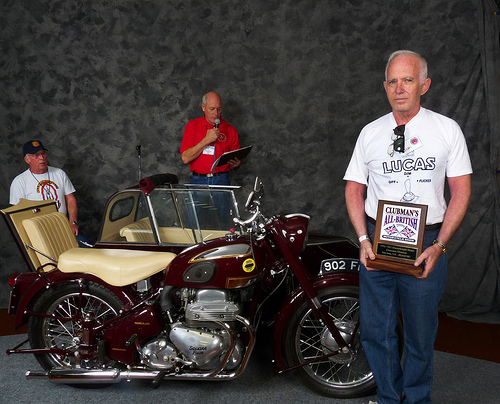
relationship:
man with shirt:
[344, 49, 474, 402] [337, 110, 473, 227]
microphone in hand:
[212, 116, 222, 133] [199, 125, 222, 145]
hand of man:
[199, 125, 222, 145] [178, 89, 241, 226]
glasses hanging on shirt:
[388, 121, 407, 156] [337, 110, 473, 227]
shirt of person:
[337, 110, 473, 227] [339, 65, 474, 396]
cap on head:
[24, 139, 44, 155] [374, 46, 437, 108]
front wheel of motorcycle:
[284, 286, 403, 395] [17, 185, 407, 388]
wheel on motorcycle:
[15, 272, 141, 394] [17, 185, 407, 388]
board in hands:
[363, 199, 428, 278] [352, 235, 438, 275]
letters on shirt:
[377, 153, 439, 176] [337, 110, 473, 227]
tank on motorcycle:
[178, 235, 275, 299] [4, 165, 428, 386]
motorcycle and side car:
[9, 197, 386, 389] [100, 143, 247, 253]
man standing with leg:
[344, 44, 474, 400] [400, 274, 445, 388]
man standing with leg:
[344, 44, 474, 400] [353, 261, 403, 401]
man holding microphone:
[177, 89, 252, 217] [205, 112, 226, 147]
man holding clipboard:
[178, 89, 241, 226] [209, 143, 254, 172]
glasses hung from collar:
[389, 123, 407, 156] [389, 104, 425, 131]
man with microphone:
[178, 89, 241, 226] [186, 118, 236, 138]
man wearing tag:
[178, 89, 241, 226] [200, 140, 216, 156]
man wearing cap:
[9, 140, 77, 238] [22, 138, 47, 160]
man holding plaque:
[344, 44, 474, 400] [368, 198, 427, 271]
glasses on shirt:
[389, 123, 407, 156] [337, 110, 473, 227]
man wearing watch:
[344, 44, 474, 400] [356, 233, 371, 245]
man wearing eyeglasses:
[9, 136, 84, 237] [29, 149, 46, 159]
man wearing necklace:
[9, 140, 77, 238] [27, 166, 55, 199]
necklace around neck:
[27, 166, 55, 199] [26, 167, 51, 174]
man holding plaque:
[344, 44, 474, 400] [364, 199, 431, 276]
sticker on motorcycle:
[235, 258, 259, 270] [1, 144, 380, 395]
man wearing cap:
[9, 140, 77, 238] [24, 141, 44, 155]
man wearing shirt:
[178, 89, 241, 226] [179, 114, 239, 173]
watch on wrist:
[430, 234, 451, 256] [430, 240, 450, 255]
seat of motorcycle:
[65, 237, 174, 286] [22, 196, 371, 376]